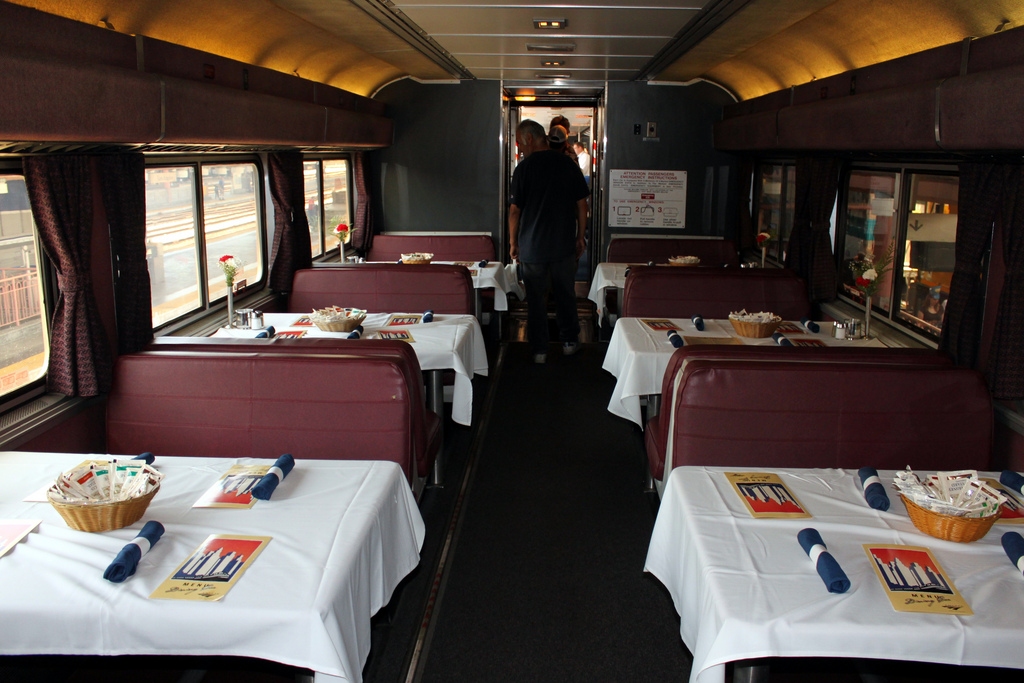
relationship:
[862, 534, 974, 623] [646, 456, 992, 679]
menu on table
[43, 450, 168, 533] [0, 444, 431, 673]
basket in middle of table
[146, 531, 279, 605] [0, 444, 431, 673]
menu on table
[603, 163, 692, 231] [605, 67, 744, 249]
white sign on wall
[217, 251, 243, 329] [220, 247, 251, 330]
flower in a vase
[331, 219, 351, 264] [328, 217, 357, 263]
flower in a vase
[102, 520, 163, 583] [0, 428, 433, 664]
blue cloth on table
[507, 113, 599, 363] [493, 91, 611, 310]
man in doorway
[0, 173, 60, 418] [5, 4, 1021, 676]
window on side of train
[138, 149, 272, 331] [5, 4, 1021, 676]
window on side of train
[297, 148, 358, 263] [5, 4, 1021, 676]
window on side of train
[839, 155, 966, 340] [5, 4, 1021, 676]
window on side of train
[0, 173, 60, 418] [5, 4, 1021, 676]
window on train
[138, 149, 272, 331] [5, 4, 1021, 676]
window on train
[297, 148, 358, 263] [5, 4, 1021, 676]
window on train